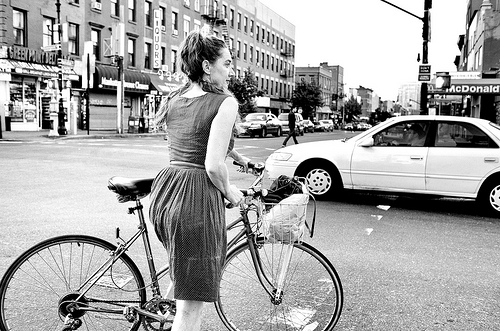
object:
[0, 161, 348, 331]
bicycle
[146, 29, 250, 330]
woman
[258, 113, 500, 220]
car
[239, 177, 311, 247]
basket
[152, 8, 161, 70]
sign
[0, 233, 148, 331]
wheel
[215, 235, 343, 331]
wheel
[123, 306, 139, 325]
pedal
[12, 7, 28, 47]
window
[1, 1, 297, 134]
building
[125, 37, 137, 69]
window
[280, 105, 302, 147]
man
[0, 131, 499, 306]
street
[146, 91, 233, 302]
dress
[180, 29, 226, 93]
hair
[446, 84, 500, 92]
mcdonalds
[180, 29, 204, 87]
ponytail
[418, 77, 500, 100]
awning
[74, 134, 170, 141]
curb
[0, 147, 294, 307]
intersection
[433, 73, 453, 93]
stoplight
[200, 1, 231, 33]
fire escape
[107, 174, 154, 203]
seat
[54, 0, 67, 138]
pole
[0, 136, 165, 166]
road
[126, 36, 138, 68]
windows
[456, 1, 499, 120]
building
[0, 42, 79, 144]
deli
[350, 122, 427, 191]
doors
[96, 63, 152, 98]
awning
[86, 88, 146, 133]
storefront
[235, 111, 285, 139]
car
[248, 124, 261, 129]
headlights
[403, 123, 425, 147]
man